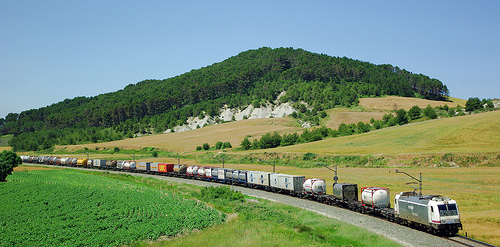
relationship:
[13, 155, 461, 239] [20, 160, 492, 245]
train traveling down tracks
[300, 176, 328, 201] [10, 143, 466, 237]
tanker part of train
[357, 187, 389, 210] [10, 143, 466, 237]
car part of train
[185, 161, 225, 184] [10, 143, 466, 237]
tanker part of train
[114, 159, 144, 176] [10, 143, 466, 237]
tanker part of train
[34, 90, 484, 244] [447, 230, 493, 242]
hillside next to track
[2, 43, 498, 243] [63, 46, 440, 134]
hill covered in trees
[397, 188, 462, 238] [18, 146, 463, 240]
locomotive on freight train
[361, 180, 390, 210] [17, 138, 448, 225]
car on train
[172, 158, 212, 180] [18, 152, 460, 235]
car on train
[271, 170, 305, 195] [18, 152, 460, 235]
cargo car on train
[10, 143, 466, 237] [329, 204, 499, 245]
train on tracks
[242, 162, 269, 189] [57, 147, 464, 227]
cargo car on train